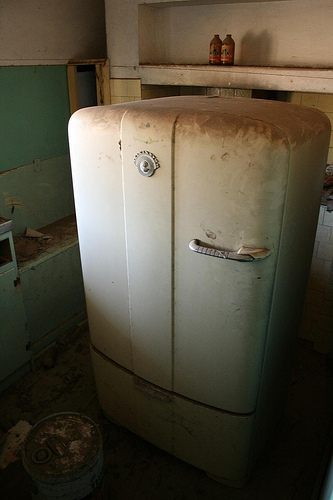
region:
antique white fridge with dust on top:
[64, 93, 331, 470]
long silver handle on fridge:
[185, 237, 273, 263]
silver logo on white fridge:
[129, 147, 158, 175]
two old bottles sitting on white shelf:
[204, 31, 235, 64]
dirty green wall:
[0, 61, 120, 167]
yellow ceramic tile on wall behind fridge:
[99, 80, 331, 320]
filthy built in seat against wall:
[14, 210, 80, 285]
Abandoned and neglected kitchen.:
[0, 0, 332, 498]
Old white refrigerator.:
[65, 93, 331, 490]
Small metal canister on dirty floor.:
[18, 409, 106, 498]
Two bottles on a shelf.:
[207, 33, 235, 68]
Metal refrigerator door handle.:
[187, 237, 272, 263]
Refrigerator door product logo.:
[132, 149, 159, 177]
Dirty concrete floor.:
[0, 307, 331, 499]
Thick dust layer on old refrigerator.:
[86, 94, 331, 149]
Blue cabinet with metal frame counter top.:
[0, 214, 37, 394]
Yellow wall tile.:
[106, 75, 141, 104]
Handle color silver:
[184, 232, 276, 270]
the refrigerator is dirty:
[50, 76, 330, 491]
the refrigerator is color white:
[58, 78, 327, 498]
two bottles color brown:
[199, 29, 236, 68]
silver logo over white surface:
[121, 142, 169, 184]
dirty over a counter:
[6, 209, 73, 265]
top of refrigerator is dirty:
[51, 76, 327, 490]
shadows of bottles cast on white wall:
[231, 31, 284, 72]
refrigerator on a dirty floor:
[12, 84, 328, 496]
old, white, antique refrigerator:
[64, 99, 332, 490]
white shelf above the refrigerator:
[139, 62, 332, 93]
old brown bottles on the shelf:
[208, 32, 236, 68]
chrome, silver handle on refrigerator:
[186, 238, 253, 262]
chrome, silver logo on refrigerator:
[131, 150, 159, 177]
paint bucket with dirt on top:
[17, 409, 104, 498]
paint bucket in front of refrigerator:
[19, 413, 104, 498]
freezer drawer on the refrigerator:
[87, 346, 256, 486]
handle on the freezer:
[132, 380, 170, 401]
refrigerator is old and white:
[63, 93, 331, 490]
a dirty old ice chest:
[65, 98, 331, 492]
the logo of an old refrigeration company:
[128, 146, 165, 181]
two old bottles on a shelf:
[197, 26, 242, 79]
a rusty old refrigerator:
[66, 73, 330, 481]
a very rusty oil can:
[20, 400, 116, 490]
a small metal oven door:
[0, 214, 45, 369]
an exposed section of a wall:
[0, 40, 115, 191]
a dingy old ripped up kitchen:
[5, 34, 320, 493]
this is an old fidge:
[49, 67, 331, 490]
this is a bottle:
[209, 28, 226, 67]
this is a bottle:
[219, 24, 240, 63]